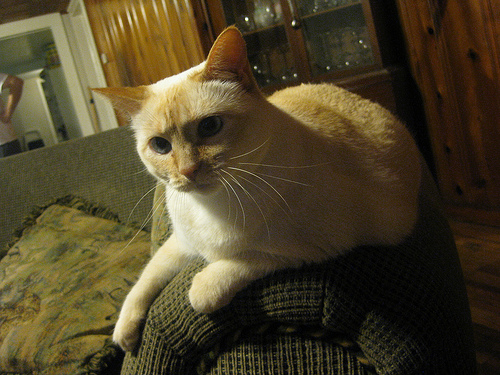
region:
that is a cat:
[84, 41, 441, 331]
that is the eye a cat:
[143, 122, 170, 163]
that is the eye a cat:
[179, 107, 232, 149]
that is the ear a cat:
[95, 77, 146, 130]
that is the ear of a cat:
[207, 18, 244, 88]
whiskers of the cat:
[214, 158, 277, 203]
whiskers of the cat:
[132, 180, 176, 216]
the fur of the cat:
[190, 193, 226, 253]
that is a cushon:
[44, 202, 145, 270]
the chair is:
[155, 295, 174, 340]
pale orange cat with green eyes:
[91, 21, 428, 351]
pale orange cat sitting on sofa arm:
[86, 21, 433, 349]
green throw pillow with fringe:
[1, 196, 166, 370]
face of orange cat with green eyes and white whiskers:
[80, 18, 320, 250]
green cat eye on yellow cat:
[143, 129, 176, 159]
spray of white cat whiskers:
[208, 138, 318, 240]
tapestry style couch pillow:
[5, 190, 158, 371]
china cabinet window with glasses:
[207, 1, 408, 98]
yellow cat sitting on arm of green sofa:
[83, 23, 437, 354]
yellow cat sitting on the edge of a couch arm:
[79, 19, 436, 356]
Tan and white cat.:
[88, 26, 423, 356]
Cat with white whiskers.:
[111, 133, 313, 245]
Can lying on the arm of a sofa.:
[87, 25, 419, 374]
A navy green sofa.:
[0, 125, 465, 374]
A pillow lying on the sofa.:
[0, 193, 150, 369]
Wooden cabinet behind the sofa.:
[186, 0, 446, 227]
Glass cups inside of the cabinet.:
[227, 0, 376, 91]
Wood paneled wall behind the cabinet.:
[85, 0, 496, 215]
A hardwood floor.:
[455, 231, 497, 371]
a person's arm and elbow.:
[0, 71, 25, 127]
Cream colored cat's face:
[92, 33, 280, 195]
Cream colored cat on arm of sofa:
[62, 27, 427, 344]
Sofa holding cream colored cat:
[0, 150, 472, 372]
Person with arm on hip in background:
[1, 72, 33, 149]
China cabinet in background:
[215, 0, 402, 112]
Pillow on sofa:
[1, 202, 153, 371]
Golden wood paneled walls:
[393, 4, 496, 219]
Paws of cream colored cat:
[107, 263, 249, 351]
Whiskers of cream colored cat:
[210, 145, 317, 220]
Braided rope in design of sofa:
[228, 324, 337, 343]